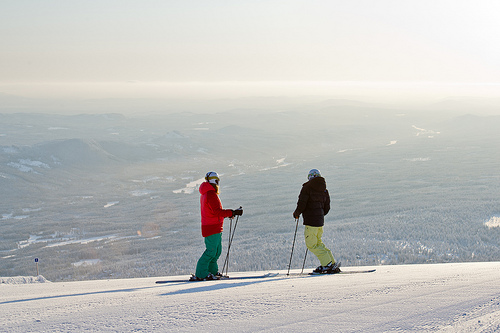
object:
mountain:
[0, 261, 500, 333]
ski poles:
[301, 247, 308, 272]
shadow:
[162, 274, 326, 296]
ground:
[0, 104, 500, 333]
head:
[205, 171, 220, 184]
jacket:
[292, 177, 331, 227]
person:
[292, 168, 341, 276]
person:
[195, 171, 243, 278]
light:
[380, 0, 500, 63]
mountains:
[0, 97, 499, 271]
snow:
[0, 259, 499, 333]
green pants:
[195, 232, 223, 279]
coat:
[199, 181, 233, 237]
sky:
[0, 1, 499, 102]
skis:
[155, 272, 279, 284]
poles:
[287, 218, 299, 275]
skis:
[309, 269, 376, 275]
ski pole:
[225, 218, 233, 275]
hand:
[233, 208, 243, 215]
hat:
[307, 168, 321, 180]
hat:
[205, 171, 219, 184]